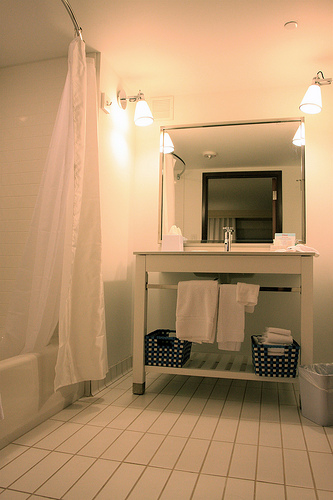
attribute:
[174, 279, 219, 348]
towel — white, large, hanging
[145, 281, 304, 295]
rod — round, for towels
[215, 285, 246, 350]
towel — white, hanging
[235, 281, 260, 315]
towel — white, hanging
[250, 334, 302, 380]
basket — blue, white, black, woven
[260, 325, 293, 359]
towels — folded, white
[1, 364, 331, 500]
floor — tiled, white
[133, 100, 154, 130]
sconce — clear, on the left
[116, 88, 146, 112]
fixture — silver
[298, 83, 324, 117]
sconce — clear, on the right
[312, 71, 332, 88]
fixture — silver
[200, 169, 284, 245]
door — brown, open, reflection, reflected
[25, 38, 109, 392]
shower curtain — white, hanging up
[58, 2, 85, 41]
rod — silver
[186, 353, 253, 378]
slats — white, wooden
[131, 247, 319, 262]
sink — white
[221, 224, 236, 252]
hardware — silver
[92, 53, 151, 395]
wall — white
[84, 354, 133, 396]
baseboard — white, tile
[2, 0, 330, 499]
bathroom — clean, bright, almost all white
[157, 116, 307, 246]
frame — silver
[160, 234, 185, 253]
tissue box — white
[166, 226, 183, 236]
tissues — sticking out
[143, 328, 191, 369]
basket — empty, black, woven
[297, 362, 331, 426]
trash bin — gray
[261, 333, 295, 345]
bath towel — folded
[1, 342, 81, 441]
bathtub — white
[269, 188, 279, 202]
door hinge — reflection